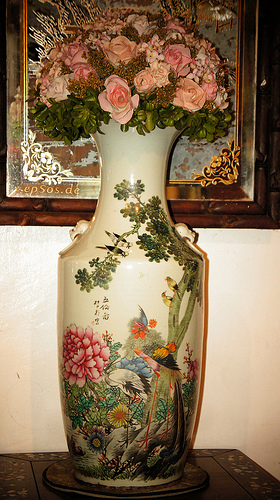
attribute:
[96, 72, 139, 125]
rose — light pink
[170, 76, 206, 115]
rose — light pink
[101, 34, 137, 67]
rose — light pink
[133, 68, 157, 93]
rose — light pink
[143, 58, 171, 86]
rose — light pink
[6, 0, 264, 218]
frame — wooden 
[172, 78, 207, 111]
pink rose — light pink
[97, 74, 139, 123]
pink rose — light pink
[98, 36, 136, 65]
pink rose — light pink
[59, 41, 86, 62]
pink rose — light pink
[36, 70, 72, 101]
pink rose — light pink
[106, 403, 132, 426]
flower — yellow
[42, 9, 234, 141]
flowers — pink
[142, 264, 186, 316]
bird — blue, yellow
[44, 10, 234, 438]
vase flowers — ceramic 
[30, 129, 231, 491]
vase — ceramic 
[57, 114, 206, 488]
vase — ceramic 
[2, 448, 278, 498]
table — wooden , brown 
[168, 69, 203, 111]
rose — pink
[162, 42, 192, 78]
rose — light pink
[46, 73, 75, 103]
rose — light pink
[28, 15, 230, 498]
flowers/vase — giant 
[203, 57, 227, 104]
flowers — pink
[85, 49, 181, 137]
flowers — pink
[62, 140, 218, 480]
vase — painted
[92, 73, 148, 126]
flower — pink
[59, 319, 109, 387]
flower — pink, large